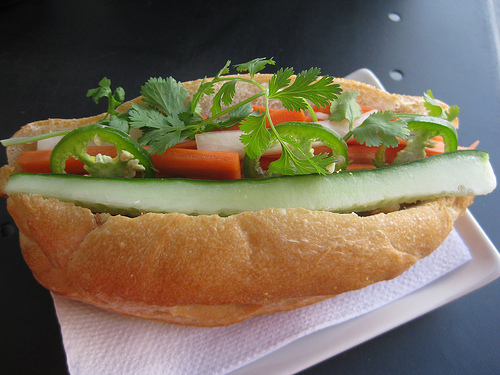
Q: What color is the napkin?
A: White.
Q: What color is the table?
A: Blue.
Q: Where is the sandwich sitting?
A: Table.